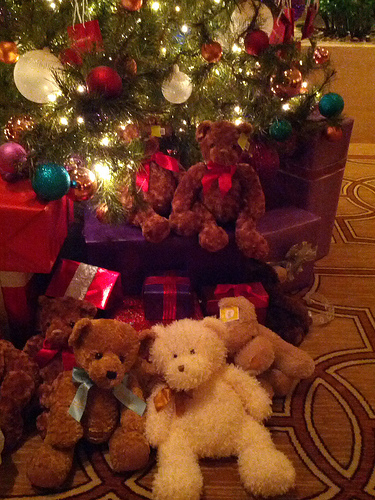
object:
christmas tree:
[0, 0, 347, 227]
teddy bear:
[22, 318, 157, 490]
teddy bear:
[0, 294, 98, 455]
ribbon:
[37, 345, 59, 363]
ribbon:
[120, 392, 148, 411]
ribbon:
[159, 388, 170, 409]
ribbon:
[163, 291, 176, 317]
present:
[141, 274, 195, 322]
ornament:
[30, 159, 71, 199]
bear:
[94, 118, 186, 245]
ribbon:
[216, 174, 230, 194]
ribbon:
[279, 158, 347, 186]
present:
[280, 111, 352, 261]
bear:
[143, 316, 296, 498]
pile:
[0, 293, 315, 498]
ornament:
[12, 48, 66, 104]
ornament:
[161, 62, 194, 105]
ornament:
[198, 38, 224, 65]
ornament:
[270, 62, 302, 92]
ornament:
[312, 42, 331, 66]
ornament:
[244, 28, 270, 60]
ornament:
[317, 91, 346, 119]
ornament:
[85, 63, 125, 105]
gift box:
[206, 281, 269, 329]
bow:
[213, 283, 269, 303]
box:
[80, 265, 123, 321]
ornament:
[0, 140, 31, 184]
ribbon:
[164, 157, 178, 172]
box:
[143, 275, 194, 322]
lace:
[162, 273, 177, 325]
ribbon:
[70, 368, 90, 398]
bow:
[202, 161, 238, 195]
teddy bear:
[169, 118, 269, 264]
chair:
[256, 191, 321, 270]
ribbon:
[78, 381, 90, 403]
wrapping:
[142, 274, 193, 322]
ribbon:
[146, 275, 164, 284]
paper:
[93, 272, 110, 295]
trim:
[61, 262, 104, 309]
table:
[0, 174, 75, 319]